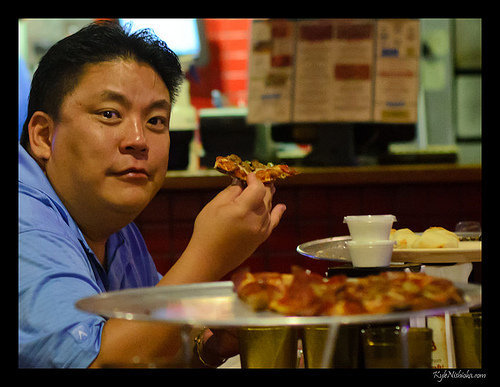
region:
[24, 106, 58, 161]
an ear of a person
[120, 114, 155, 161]
a nose of a person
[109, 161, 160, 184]
a mouth of person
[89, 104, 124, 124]
an eye of a person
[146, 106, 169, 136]
an eye of a person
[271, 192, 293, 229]
a pinky finger on a hand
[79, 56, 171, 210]
the face of a person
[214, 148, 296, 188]
a hand holding a piece of pizza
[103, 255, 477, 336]
half of a pizza on a pan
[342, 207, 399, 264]
two tubs of a sauce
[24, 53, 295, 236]
Man holding a piece of pizza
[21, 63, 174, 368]
Man wearing blue shirt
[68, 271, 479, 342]
Pizza on a silver baking sheet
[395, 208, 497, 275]
Pieces of bread on silver baking sheet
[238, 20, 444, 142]
Restaurant menu on the counter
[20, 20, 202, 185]
Man has black hair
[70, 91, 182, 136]
Man has brown eyes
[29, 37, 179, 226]
Man looks to be Asian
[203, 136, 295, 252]
Holding pizza with right hand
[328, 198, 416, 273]
Containers of dipping sauce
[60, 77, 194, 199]
The man is asian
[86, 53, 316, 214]
the asian man is eating pizza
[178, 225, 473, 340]
a half eaten pizza pie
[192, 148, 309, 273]
the pizza is in the man's right hand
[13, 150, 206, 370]
man wearing a blue shirt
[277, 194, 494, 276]
one finished pizza pie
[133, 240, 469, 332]
pizza topped with peperoni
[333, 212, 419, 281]
a side of dressing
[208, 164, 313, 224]
holding the pizza by it's crust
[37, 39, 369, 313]
man in blue shirt eating pizza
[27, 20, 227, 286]
a man in blue shirt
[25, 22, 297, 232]
man holding slice of pizza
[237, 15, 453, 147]
blurry menu in background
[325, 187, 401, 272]
small plastic containers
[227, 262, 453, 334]
slices of pizza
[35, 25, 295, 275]
man eating pizza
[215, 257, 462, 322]
pepperoni is on pizza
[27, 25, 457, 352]
man eating in a resturant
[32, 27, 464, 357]
man at pizza parlor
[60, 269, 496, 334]
pizza on silver pan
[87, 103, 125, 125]
human eye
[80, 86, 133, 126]
human eye and eyebrow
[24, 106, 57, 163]
human right ear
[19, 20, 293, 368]
man holding a piece of pizza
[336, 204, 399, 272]
one sauce container stacked on another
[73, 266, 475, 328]
metal platter holding pizza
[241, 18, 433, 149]
blurry menu in the distance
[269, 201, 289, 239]
pinky finger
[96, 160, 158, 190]
mouth with a small smile